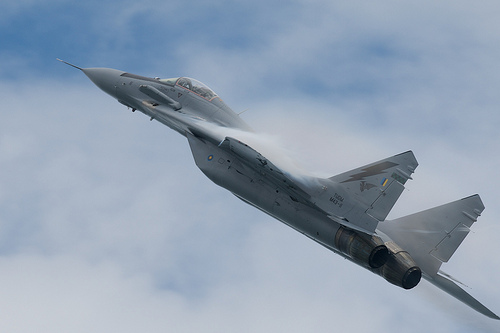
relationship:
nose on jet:
[48, 50, 123, 98] [53, 56, 498, 322]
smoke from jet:
[198, 115, 318, 177] [53, 57, 500, 320]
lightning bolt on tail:
[335, 156, 398, 188] [323, 145, 498, 322]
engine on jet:
[357, 234, 419, 294] [53, 57, 500, 320]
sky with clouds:
[31, 19, 443, 330] [23, 111, 179, 325]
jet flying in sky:
[53, 57, 500, 320] [0, 3, 498, 331]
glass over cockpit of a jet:
[157, 71, 217, 103] [53, 57, 500, 320]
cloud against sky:
[0, 0, 499, 331] [1, 2, 419, 307]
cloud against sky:
[0, 0, 499, 331] [0, 3, 498, 331]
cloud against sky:
[12, 249, 197, 331] [0, 3, 498, 331]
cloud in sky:
[0, 0, 499, 331] [20, 169, 170, 329]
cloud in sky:
[0, 0, 499, 331] [7, 117, 232, 292]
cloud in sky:
[0, 0, 499, 331] [5, 183, 248, 323]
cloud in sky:
[0, 0, 499, 331] [1, 205, 297, 315]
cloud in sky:
[0, 0, 499, 331] [0, 3, 498, 331]